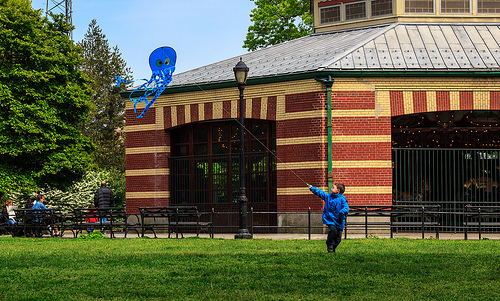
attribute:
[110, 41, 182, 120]
kite — shaped, octopus, blue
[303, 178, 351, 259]
kid — young, running, alone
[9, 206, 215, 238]
benches — black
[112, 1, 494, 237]
house — red, yellow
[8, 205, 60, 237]
bench — black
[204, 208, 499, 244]
fence — black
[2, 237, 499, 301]
field — grassy, green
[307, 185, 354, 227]
jacket — blue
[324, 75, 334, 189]
pipe — green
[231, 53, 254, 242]
lamp post — black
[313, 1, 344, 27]
window — framed